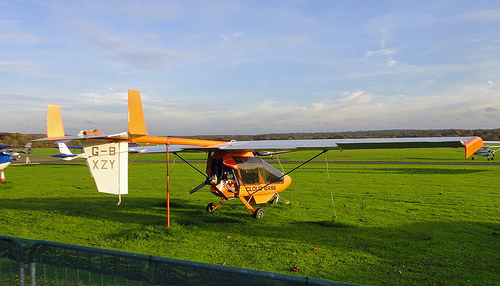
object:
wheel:
[250, 206, 268, 224]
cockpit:
[225, 150, 286, 191]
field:
[2, 117, 500, 283]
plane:
[0, 137, 43, 183]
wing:
[183, 127, 491, 162]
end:
[114, 86, 159, 140]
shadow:
[0, 176, 500, 286]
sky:
[2, 1, 499, 141]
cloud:
[76, 31, 500, 122]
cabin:
[198, 151, 294, 211]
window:
[230, 152, 289, 187]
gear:
[200, 196, 222, 216]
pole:
[164, 144, 172, 230]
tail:
[98, 82, 159, 141]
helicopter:
[11, 89, 487, 228]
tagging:
[79, 131, 138, 210]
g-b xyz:
[86, 143, 121, 174]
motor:
[182, 156, 235, 205]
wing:
[26, 103, 129, 148]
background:
[5, 7, 500, 213]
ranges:
[4, 126, 500, 165]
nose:
[1, 154, 15, 169]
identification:
[78, 130, 132, 200]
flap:
[19, 132, 129, 146]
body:
[166, 136, 306, 221]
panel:
[210, 171, 229, 183]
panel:
[210, 156, 225, 165]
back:
[179, 148, 247, 207]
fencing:
[1, 230, 438, 286]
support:
[237, 195, 255, 214]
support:
[214, 197, 229, 212]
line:
[271, 145, 293, 178]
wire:
[319, 150, 340, 223]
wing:
[71, 132, 131, 199]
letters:
[78, 144, 119, 174]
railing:
[0, 228, 403, 286]